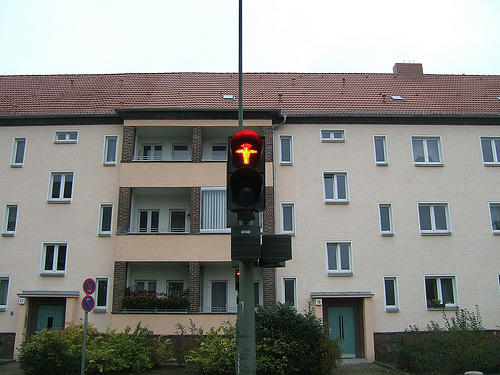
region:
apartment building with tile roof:
[3, 59, 498, 361]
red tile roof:
[1, 72, 499, 120]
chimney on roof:
[392, 58, 426, 76]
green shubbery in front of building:
[18, 295, 349, 370]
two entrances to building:
[13, 285, 373, 365]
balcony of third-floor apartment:
[117, 115, 276, 168]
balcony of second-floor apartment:
[116, 182, 203, 234]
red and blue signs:
[81, 273, 96, 312]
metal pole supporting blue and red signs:
[78, 310, 89, 372]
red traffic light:
[226, 126, 292, 373]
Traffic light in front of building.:
[214, 128, 289, 373]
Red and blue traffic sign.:
[70, 277, 105, 321]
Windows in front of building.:
[312, 121, 471, 287]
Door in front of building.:
[312, 290, 388, 367]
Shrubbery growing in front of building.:
[20, 299, 342, 374]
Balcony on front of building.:
[126, 185, 206, 242]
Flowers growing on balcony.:
[121, 285, 195, 316]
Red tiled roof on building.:
[18, 66, 226, 126]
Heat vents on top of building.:
[272, 71, 391, 107]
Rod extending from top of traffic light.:
[221, 2, 262, 127]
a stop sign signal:
[231, 130, 272, 184]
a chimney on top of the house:
[388, 52, 443, 80]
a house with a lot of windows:
[2, 113, 499, 373]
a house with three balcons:
[112, 117, 236, 342]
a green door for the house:
[328, 297, 363, 362]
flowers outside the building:
[21, 307, 326, 374]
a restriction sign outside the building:
[75, 270, 109, 314]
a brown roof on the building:
[284, 70, 355, 112]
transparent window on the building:
[405, 177, 457, 243]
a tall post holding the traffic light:
[223, 26, 290, 373]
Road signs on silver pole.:
[56, 275, 98, 374]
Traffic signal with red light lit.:
[228, 101, 295, 374]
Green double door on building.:
[316, 292, 376, 359]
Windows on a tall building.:
[413, 197, 458, 309]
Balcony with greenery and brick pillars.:
[109, 249, 244, 313]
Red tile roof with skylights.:
[9, 73, 496, 110]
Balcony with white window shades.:
[111, 188, 227, 230]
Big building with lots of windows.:
[31, 43, 498, 373]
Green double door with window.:
[16, 281, 82, 366]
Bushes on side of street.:
[16, 308, 498, 372]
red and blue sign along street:
[70, 268, 97, 333]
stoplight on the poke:
[227, 117, 267, 216]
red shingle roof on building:
[7, 74, 499, 117]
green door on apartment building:
[319, 285, 380, 363]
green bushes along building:
[27, 313, 373, 370]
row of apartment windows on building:
[407, 132, 466, 316]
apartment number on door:
[11, 282, 35, 314]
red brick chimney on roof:
[372, 42, 449, 84]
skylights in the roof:
[372, 80, 424, 105]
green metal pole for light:
[230, 257, 278, 372]